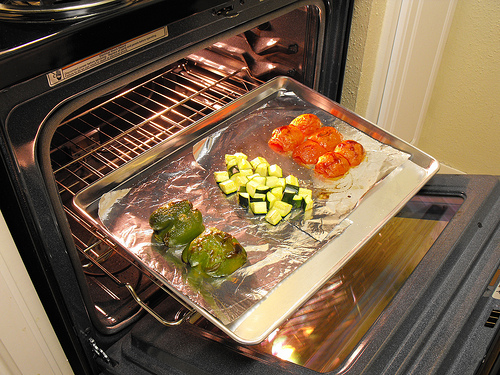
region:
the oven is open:
[27, 35, 424, 352]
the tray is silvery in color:
[151, 134, 355, 262]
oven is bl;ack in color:
[414, 289, 486, 374]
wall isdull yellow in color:
[456, 47, 498, 128]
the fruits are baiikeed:
[156, 198, 238, 279]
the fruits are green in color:
[155, 194, 267, 300]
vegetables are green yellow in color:
[228, 162, 282, 229]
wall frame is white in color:
[383, 19, 414, 121]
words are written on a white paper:
[46, 39, 172, 71]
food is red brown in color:
[270, 119, 350, 176]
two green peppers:
[141, 204, 253, 281]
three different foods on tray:
[160, 119, 387, 283]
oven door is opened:
[147, 317, 498, 374]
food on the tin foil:
[157, 101, 338, 292]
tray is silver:
[304, 209, 359, 334]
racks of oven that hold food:
[56, 78, 212, 132]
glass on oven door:
[286, 284, 386, 367]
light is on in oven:
[201, 47, 286, 82]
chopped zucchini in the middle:
[223, 149, 327, 220]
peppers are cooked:
[122, 208, 242, 291]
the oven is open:
[68, 63, 428, 363]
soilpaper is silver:
[176, 163, 209, 189]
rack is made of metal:
[117, 95, 160, 125]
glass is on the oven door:
[360, 250, 389, 311]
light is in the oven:
[186, 41, 238, 106]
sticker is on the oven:
[58, 48, 161, 63]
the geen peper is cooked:
[142, 198, 201, 250]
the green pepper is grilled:
[192, 235, 248, 275]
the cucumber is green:
[221, 156, 315, 220]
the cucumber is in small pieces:
[212, 150, 308, 227]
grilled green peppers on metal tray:
[142, 179, 259, 310]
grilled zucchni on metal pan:
[205, 140, 315, 246]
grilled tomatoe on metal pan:
[262, 104, 389, 206]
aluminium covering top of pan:
[82, 112, 412, 322]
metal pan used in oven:
[65, 75, 445, 344]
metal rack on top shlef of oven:
[68, 90, 301, 180]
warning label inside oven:
[32, 27, 214, 84]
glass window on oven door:
[264, 164, 445, 374]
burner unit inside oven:
[74, 229, 146, 320]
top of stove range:
[1, 2, 378, 72]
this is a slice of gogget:
[266, 203, 289, 230]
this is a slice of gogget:
[273, 171, 303, 196]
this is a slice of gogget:
[203, 167, 232, 184]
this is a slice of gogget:
[243, 178, 260, 195]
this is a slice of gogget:
[267, 171, 283, 193]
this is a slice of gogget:
[212, 178, 246, 199]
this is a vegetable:
[180, 220, 245, 277]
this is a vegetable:
[156, 185, 202, 245]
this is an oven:
[22, 2, 497, 374]